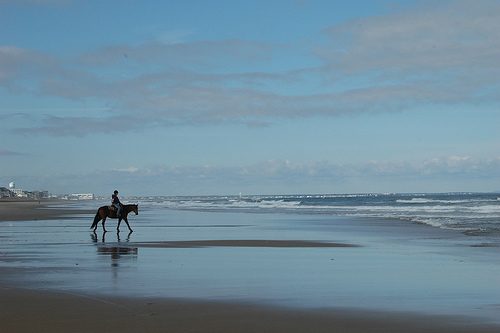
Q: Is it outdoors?
A: Yes, it is outdoors.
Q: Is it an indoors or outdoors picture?
A: It is outdoors.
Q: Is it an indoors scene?
A: No, it is outdoors.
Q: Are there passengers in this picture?
A: No, there are no passengers.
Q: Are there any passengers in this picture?
A: No, there are no passengers.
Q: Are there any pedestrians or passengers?
A: No, there are no passengers or pedestrians.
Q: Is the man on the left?
A: Yes, the man is on the left of the image.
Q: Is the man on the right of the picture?
A: No, the man is on the left of the image.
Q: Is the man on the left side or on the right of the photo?
A: The man is on the left of the image.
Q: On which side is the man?
A: The man is on the left of the image.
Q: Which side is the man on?
A: The man is on the left of the image.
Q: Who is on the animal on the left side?
A: The man is on the horse.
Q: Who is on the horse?
A: The man is on the horse.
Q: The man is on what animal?
A: The man is on the horse.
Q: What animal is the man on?
A: The man is on the horse.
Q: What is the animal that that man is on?
A: The animal is a horse.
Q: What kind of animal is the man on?
A: The man is on the horse.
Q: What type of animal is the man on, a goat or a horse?
A: The man is on a horse.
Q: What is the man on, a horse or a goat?
A: The man is on a horse.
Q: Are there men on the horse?
A: Yes, there is a man on the horse.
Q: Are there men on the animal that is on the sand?
A: Yes, there is a man on the horse.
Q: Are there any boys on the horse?
A: No, there is a man on the horse.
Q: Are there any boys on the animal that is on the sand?
A: No, there is a man on the horse.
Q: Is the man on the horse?
A: Yes, the man is on the horse.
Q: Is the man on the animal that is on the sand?
A: Yes, the man is on the horse.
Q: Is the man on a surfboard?
A: No, the man is on the horse.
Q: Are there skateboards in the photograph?
A: No, there are no skateboards.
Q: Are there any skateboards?
A: No, there are no skateboards.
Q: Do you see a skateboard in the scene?
A: No, there are no skateboards.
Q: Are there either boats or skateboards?
A: No, there are no skateboards or boats.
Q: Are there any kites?
A: No, there are no kites.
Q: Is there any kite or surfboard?
A: No, there are no kites or surfboards.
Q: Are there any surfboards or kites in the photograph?
A: No, there are no kites or surfboards.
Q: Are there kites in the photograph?
A: No, there are no kites.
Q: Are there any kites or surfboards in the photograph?
A: No, there are no kites or surfboards.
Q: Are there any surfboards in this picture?
A: No, there are no surfboards.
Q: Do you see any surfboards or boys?
A: No, there are no surfboards or boys.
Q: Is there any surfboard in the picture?
A: No, there are no surfboards.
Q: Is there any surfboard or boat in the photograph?
A: No, there are no surfboards or boats.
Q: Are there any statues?
A: No, there are no statues.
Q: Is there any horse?
A: Yes, there is a horse.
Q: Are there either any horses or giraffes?
A: Yes, there is a horse.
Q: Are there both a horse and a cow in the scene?
A: No, there is a horse but no cows.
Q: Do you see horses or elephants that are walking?
A: Yes, the horse is walking.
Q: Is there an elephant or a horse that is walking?
A: Yes, the horse is walking.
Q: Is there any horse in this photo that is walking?
A: Yes, there is a horse that is walking.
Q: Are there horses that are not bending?
A: Yes, there is a horse that is walking.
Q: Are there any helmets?
A: No, there are no helmets.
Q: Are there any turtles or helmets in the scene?
A: No, there are no helmets or turtles.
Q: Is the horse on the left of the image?
A: Yes, the horse is on the left of the image.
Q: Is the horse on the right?
A: No, the horse is on the left of the image.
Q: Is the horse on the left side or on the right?
A: The horse is on the left of the image.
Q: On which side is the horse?
A: The horse is on the left of the image.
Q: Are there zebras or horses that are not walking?
A: No, there is a horse but it is walking.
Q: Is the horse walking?
A: Yes, the horse is walking.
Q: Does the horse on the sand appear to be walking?
A: Yes, the horse is walking.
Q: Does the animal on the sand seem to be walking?
A: Yes, the horse is walking.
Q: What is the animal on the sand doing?
A: The horse is walking.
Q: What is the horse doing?
A: The horse is walking.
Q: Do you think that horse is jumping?
A: No, the horse is walking.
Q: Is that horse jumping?
A: No, the horse is walking.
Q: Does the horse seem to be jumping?
A: No, the horse is walking.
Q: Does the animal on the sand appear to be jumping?
A: No, the horse is walking.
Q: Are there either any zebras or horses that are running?
A: No, there is a horse but it is walking.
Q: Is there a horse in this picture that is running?
A: No, there is a horse but it is walking.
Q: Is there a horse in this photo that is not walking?
A: No, there is a horse but it is walking.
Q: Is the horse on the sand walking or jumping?
A: The horse is walking.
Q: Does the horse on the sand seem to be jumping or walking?
A: The horse is walking.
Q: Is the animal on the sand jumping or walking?
A: The horse is walking.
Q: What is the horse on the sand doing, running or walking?
A: The horse is walking.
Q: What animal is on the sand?
A: The animal is a horse.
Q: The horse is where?
A: The horse is on the sand.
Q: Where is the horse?
A: The horse is on the sand.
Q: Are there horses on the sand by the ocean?
A: Yes, there is a horse on the sand.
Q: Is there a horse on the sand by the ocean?
A: Yes, there is a horse on the sand.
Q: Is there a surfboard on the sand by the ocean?
A: No, there is a horse on the sand.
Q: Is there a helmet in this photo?
A: No, there are no helmets.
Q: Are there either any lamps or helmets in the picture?
A: No, there are no helmets or lamps.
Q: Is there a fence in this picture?
A: No, there are no fences.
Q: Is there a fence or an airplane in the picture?
A: No, there are no fences or airplanes.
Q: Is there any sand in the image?
A: Yes, there is sand.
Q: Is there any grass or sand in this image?
A: Yes, there is sand.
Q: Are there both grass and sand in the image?
A: No, there is sand but no grass.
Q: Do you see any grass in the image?
A: No, there is no grass.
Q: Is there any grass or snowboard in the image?
A: No, there are no grass or snowboards.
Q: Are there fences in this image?
A: No, there are no fences.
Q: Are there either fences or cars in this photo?
A: No, there are no fences or cars.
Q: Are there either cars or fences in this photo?
A: No, there are no fences or cars.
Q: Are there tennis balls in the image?
A: No, there are no tennis balls.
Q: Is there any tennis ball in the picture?
A: No, there are no tennis balls.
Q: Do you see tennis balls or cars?
A: No, there are no tennis balls or cars.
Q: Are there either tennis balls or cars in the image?
A: No, there are no tennis balls or cars.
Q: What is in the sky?
A: The clouds are in the sky.